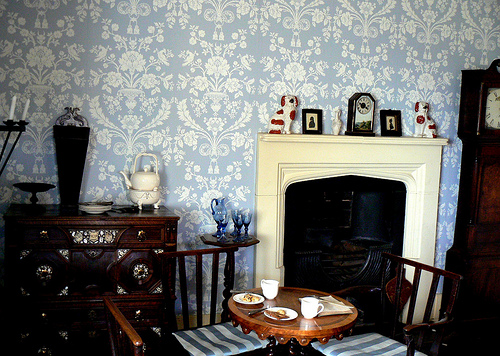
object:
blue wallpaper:
[71, 44, 240, 99]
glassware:
[210, 197, 254, 244]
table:
[200, 231, 261, 291]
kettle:
[118, 151, 164, 212]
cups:
[261, 279, 281, 301]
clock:
[344, 93, 374, 136]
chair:
[309, 247, 463, 356]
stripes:
[308, 333, 421, 356]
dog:
[268, 95, 300, 134]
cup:
[299, 297, 324, 319]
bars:
[227, 286, 360, 356]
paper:
[305, 295, 353, 319]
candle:
[9, 95, 17, 122]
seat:
[311, 333, 423, 356]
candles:
[22, 99, 31, 120]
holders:
[0, 119, 30, 172]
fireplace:
[285, 170, 405, 325]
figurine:
[414, 100, 437, 138]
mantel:
[257, 135, 447, 321]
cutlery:
[247, 308, 266, 316]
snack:
[265, 306, 293, 317]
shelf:
[0, 202, 180, 356]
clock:
[479, 82, 500, 134]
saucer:
[264, 306, 298, 320]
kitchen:
[0, 0, 500, 356]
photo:
[302, 109, 323, 134]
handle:
[133, 153, 158, 175]